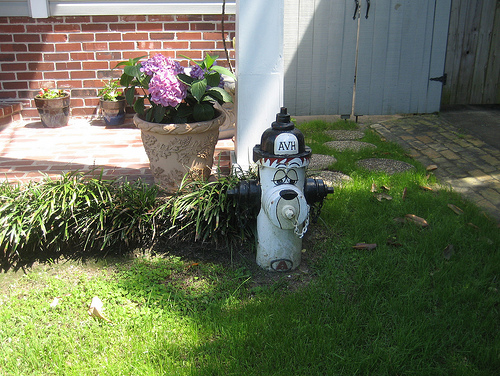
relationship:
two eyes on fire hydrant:
[268, 173, 313, 189] [219, 105, 335, 275]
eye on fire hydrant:
[271, 169, 286, 185] [219, 105, 335, 275]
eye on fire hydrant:
[287, 169, 298, 186] [219, 105, 335, 275]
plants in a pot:
[95, 76, 120, 99] [134, 106, 225, 192]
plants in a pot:
[34, 87, 69, 98] [100, 97, 125, 124]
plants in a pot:
[114, 51, 234, 118] [34, 90, 69, 126]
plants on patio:
[95, 76, 120, 99] [0, 117, 235, 184]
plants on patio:
[34, 87, 69, 98] [0, 117, 235, 184]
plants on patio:
[114, 51, 234, 118] [0, 117, 235, 184]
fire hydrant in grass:
[219, 105, 335, 275] [0, 188, 498, 374]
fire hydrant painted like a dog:
[219, 105, 335, 275] [256, 162, 308, 254]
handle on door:
[353, 0, 361, 19] [273, 1, 447, 116]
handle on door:
[351, 0, 360, 21] [273, 1, 447, 116]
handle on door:
[360, 0, 374, 16] [273, 1, 447, 116]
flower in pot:
[138, 55, 185, 77] [139, 98, 219, 195]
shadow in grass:
[124, 158, 497, 373] [0, 188, 498, 374]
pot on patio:
[25, 86, 73, 128] [8, 119, 493, 217]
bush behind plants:
[5, 173, 258, 243] [34, 87, 69, 98]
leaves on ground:
[348, 173, 461, 258] [6, 181, 481, 373]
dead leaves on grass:
[368, 178, 391, 202] [3, 122, 498, 371]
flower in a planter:
[135, 55, 180, 74] [133, 112, 225, 192]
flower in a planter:
[144, 67, 187, 107] [133, 112, 225, 192]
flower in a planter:
[179, 56, 234, 106] [133, 112, 225, 192]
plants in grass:
[10, 180, 230, 245] [173, 281, 448, 366]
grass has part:
[3, 258, 169, 355] [7, 267, 196, 370]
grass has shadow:
[3, 258, 169, 355] [199, 190, 498, 367]